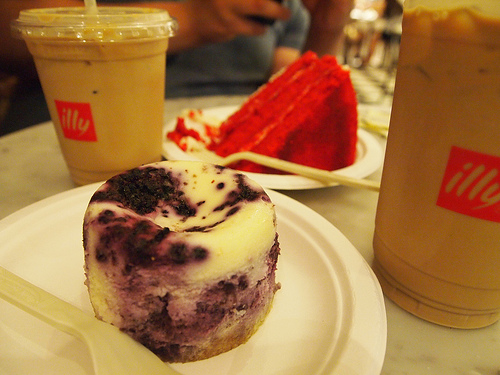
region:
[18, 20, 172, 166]
a cup on the table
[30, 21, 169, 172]
a drink on the table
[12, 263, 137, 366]
a fork on the plate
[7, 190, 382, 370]
a paper plate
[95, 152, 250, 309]
food on the plate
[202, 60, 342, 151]
cake on a plate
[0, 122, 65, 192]
the white table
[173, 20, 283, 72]
a person sitting at the table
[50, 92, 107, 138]
writing on the cup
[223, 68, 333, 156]
a red piece of cake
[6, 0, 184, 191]
The cup of coffee on the table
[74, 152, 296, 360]
The pastry on the plate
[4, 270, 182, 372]
The fork on the plate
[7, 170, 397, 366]
The plate is the color white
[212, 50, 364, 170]
The cake on the plate is red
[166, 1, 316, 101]
The person has on a grat top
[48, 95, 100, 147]
The logo on the cup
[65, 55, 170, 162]
The color of the drink is brown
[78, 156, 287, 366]
a pastry on plate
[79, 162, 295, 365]
a cake on white plate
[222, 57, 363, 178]
red cake on plate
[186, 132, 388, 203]
white fork by cake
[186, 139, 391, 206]
white fork on plate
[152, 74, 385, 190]
white plate on table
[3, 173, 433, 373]
white plate on table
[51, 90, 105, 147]
red symbol on cup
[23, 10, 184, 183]
brown liquid in cup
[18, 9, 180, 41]
clear lid on cup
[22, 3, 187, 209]
this is a cup of coffee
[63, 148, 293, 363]
this is a small cake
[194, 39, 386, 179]
this is a red cake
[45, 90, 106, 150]
the logo of a coffee company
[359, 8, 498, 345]
a cup of iced coffee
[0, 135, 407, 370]
the cake is on a paper plate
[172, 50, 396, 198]
this is a slice of red velvet cake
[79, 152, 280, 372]
this cake has blueberries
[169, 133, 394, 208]
this is a plastic fork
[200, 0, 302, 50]
a hand holding a cell phone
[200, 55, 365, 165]
Red velvet layer cake.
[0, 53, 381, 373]
White paper plates with desserts on top.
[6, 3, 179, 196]
Ice coffee in clear plastic cup.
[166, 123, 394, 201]
White plastic fork on plate.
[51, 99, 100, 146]
Red logo on side of cup.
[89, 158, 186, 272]
Purple fruit in dessert.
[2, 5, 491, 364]
Iced coffee and desserts on table.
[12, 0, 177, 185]
plastic cup filled with coffee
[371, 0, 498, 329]
plastic cup filled with coffee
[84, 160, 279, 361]
piece of blueberry cheescake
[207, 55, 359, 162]
piece of red velvet cake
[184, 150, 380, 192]
a white plastic fork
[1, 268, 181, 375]
a white plastic fork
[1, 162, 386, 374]
white plate with cheescake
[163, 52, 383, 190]
white plate with red velvet cake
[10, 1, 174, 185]
plastic cup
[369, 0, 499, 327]
plastic cup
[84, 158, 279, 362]
purple and white roung dessert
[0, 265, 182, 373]
plastic fork next to the purple and white dessert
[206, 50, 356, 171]
a slice of red cake on the plate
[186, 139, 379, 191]
white plastic fork next to the cake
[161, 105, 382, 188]
white plate the cake is on